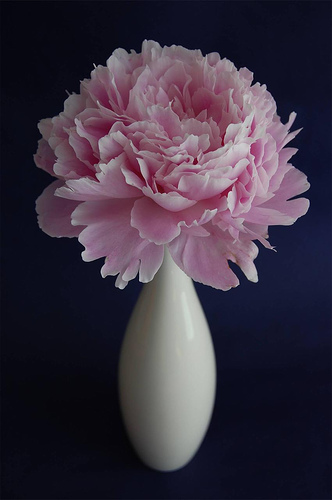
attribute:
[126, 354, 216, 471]
jug — bottom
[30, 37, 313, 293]
flower — pink, part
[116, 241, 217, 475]
vase — white, reflective, slim, edge, side, curved, tall, shiny, base, slender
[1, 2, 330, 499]
room — blue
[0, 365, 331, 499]
table — blue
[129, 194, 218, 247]
petal — curved, pointed